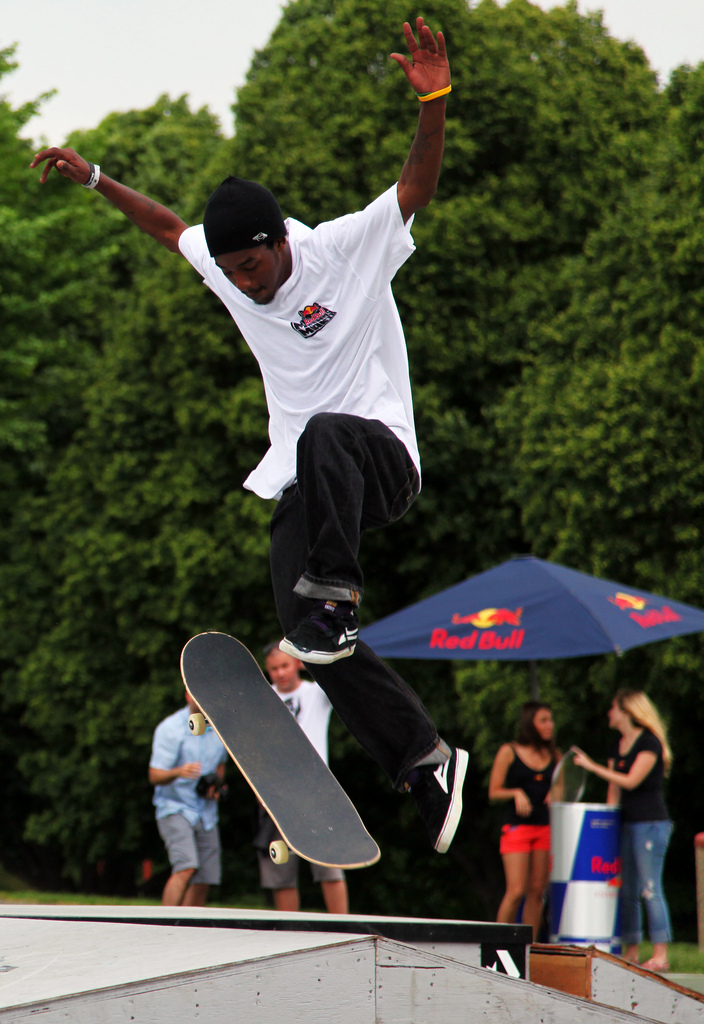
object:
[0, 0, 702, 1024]
field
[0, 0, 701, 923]
trees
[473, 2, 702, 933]
tree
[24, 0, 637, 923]
tree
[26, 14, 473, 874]
skater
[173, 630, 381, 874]
skateboard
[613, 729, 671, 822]
black top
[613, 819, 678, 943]
jeans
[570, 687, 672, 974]
woman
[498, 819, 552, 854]
red shorts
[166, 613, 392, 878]
air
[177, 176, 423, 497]
shirt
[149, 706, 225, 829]
shirt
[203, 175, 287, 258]
hat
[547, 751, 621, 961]
cooler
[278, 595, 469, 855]
shoes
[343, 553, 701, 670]
umbrella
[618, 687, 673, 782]
hair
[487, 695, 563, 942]
woman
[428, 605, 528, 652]
logo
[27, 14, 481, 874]
trick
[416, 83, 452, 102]
bracelets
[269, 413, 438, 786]
jeans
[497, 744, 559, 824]
tank top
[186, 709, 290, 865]
wheels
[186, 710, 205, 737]
wheel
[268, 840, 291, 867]
wheel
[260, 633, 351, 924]
man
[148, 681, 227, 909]
man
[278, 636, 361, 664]
sole